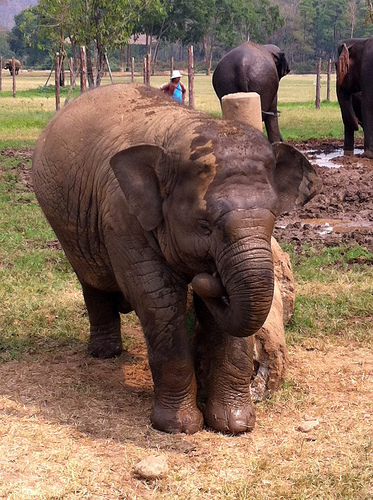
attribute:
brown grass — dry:
[0, 334, 372, 497]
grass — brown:
[2, 352, 357, 484]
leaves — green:
[122, 4, 213, 38]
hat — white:
[168, 67, 185, 80]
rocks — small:
[138, 415, 318, 472]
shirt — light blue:
[169, 84, 186, 102]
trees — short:
[17, 0, 372, 109]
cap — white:
[169, 66, 182, 77]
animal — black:
[210, 40, 290, 142]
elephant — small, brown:
[28, 83, 320, 434]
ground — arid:
[0, 68, 371, 498]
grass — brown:
[12, 255, 75, 354]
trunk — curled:
[185, 247, 278, 338]